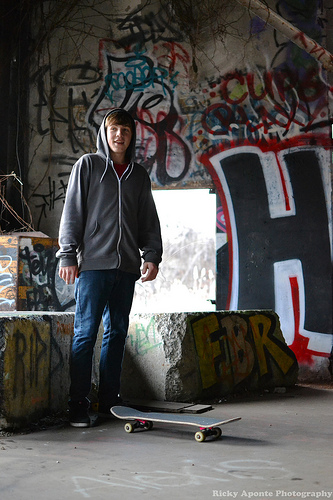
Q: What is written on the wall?
A: Graffiti.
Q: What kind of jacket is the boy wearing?
A: A hoodie.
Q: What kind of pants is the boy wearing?
A: Blue jeans.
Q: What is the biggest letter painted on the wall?
A: H.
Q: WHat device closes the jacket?
A: Zipper.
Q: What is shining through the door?
A: The sun.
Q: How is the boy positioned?
A: Standing.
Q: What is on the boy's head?
A: A hood.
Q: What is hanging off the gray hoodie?
A: Strings.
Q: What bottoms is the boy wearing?
A: Jeans.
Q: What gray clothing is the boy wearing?
A: A hoodie.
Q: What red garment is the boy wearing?
A: A tee shirt.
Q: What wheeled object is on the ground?
A: A skateboard.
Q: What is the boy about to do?
A: Skate.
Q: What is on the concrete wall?
A: Graffiti.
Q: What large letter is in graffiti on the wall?
A: H.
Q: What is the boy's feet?
A: Shoes.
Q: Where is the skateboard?
A: On the ground.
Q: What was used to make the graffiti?
A: Spray paint.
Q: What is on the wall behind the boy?
A: Graffiti.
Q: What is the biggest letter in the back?
A: H.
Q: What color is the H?
A: Black.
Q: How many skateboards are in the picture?
A: One.